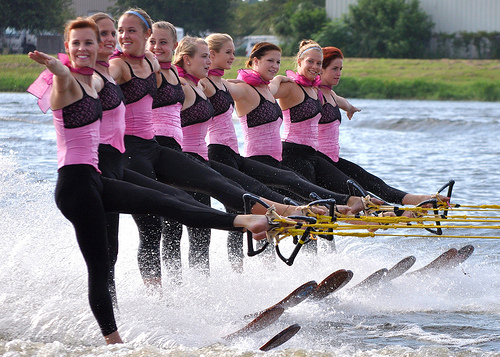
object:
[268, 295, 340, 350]
splash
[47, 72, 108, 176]
tank top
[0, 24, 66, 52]
building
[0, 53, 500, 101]
grass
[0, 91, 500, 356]
water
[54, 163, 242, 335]
pants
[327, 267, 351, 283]
edge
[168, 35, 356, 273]
women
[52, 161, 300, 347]
leggings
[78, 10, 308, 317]
ladies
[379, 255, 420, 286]
surfboards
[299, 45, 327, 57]
headband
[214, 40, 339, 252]
lady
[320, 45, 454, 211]
lady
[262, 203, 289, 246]
metal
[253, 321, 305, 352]
ski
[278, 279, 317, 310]
ski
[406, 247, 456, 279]
ski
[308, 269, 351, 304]
ski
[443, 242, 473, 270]
ski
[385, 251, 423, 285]
ski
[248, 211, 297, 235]
foot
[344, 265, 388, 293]
board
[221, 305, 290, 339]
board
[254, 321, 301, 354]
board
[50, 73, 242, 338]
outfit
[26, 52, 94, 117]
scarf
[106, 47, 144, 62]
scarf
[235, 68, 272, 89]
scarf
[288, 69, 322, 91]
scarf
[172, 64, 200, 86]
scarf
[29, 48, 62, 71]
woman's hand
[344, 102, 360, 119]
woman's hand